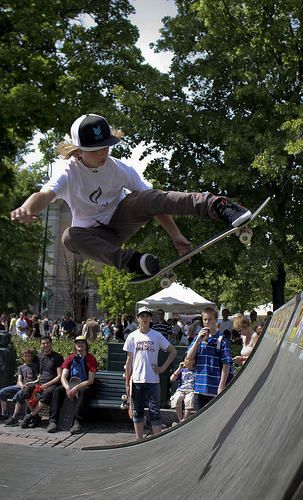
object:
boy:
[11, 112, 251, 278]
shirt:
[43, 156, 154, 229]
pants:
[60, 188, 229, 272]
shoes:
[134, 251, 160, 278]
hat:
[71, 112, 120, 152]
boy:
[46, 335, 97, 433]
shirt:
[60, 355, 99, 377]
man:
[170, 353, 195, 424]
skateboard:
[127, 197, 271, 290]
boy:
[185, 306, 233, 411]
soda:
[202, 326, 209, 343]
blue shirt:
[184, 328, 231, 396]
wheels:
[160, 276, 171, 291]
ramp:
[4, 295, 301, 498]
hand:
[173, 236, 195, 258]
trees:
[157, 3, 301, 317]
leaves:
[214, 2, 246, 56]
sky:
[24, 0, 207, 189]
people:
[0, 348, 36, 427]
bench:
[81, 371, 168, 433]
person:
[122, 306, 178, 440]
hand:
[151, 363, 160, 374]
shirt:
[122, 327, 170, 384]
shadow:
[199, 297, 302, 479]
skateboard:
[120, 364, 134, 420]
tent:
[137, 281, 221, 315]